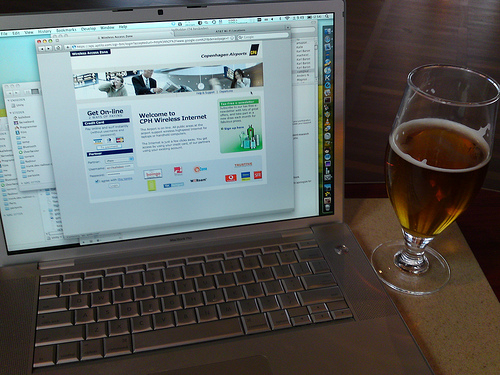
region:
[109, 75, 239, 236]
a laptop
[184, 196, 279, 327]
a laptop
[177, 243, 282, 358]
a laptop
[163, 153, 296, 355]
a laptop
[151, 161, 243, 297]
a laptop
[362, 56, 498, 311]
a clear glass of beer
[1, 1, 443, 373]
a laptop with a news article on display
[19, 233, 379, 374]
the keyboard on the laptop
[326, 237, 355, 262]
a button to the right of the keyboard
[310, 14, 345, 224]
the task bar on the laptop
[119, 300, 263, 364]
the space bar key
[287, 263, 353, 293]
the enter key on the keyboard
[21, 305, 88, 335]
the caps lock key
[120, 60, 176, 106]
a man in a black suit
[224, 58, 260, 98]
a woman with black hair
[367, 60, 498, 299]
THE BEER IS IN THE GLASS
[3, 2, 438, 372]
THE LAPTOP IS GREY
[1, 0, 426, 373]
THE LAPTOP IS ON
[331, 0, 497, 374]
THE DESK IS WOODEN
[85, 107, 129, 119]
THE WEBSITE SAYS GET ON-LINE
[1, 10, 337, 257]
SEVERAL WEB PAGES ARE OPEN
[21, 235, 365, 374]
THE LAPTOP HAS MANY KEYS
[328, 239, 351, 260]
THE POWER KEY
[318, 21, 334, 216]
THE TASK BAR IS ON THE RIGHT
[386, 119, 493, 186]
THE BEAR HAS FOAM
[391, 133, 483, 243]
Beer in a glass goblet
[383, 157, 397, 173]
Red marking on a goblet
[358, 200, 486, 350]
Glass on a desk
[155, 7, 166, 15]
Camera on a laptop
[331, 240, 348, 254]
Power button on a laptop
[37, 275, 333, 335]
Keyboard on a laptop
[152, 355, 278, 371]
Touch pad on a laptop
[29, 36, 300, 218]
Window open on a monitor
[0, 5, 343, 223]
Open laptop monitor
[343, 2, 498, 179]
Brown desk top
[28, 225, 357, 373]
the keyboard of a laptop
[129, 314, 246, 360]
the space bar on a keyboard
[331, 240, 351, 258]
a button on the laptop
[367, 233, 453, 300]
the base of a glass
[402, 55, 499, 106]
the mouth of a glass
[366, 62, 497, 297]
a drinking glass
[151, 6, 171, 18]
a webcam on the laptop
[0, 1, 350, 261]
the screen of the laptop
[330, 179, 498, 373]
the table under the laptop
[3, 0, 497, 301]
a brown wooden floor